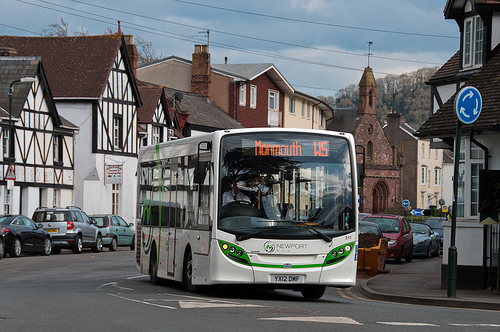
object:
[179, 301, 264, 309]
markings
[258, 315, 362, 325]
markings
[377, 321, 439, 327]
markings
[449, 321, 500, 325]
markings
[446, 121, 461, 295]
pole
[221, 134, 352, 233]
windscreen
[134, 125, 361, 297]
bus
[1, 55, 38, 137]
roof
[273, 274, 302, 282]
license plate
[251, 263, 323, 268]
lines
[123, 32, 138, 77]
chimney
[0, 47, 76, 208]
building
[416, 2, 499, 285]
building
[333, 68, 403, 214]
building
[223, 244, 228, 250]
bus headlights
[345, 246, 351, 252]
bus headlights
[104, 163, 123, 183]
sign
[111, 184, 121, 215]
door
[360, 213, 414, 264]
car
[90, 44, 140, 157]
trim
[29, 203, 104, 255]
vehicle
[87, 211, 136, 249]
vehicle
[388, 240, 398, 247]
headlight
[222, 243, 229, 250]
headlight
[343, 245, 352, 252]
headlight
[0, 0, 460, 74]
sky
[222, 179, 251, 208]
driver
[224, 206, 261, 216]
wheel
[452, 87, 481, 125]
sign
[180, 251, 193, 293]
wheel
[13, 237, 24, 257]
wheel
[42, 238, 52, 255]
wheel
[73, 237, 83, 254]
wheel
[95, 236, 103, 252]
wheel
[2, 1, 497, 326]
village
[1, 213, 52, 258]
cars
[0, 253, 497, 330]
street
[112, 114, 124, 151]
window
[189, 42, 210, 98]
chimney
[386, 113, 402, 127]
chimney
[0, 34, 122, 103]
roof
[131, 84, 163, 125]
roof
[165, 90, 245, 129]
roof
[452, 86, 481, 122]
street sign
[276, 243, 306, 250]
name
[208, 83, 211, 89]
bricks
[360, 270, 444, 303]
corner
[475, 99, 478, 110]
lines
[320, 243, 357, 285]
panel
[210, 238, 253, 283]
panel